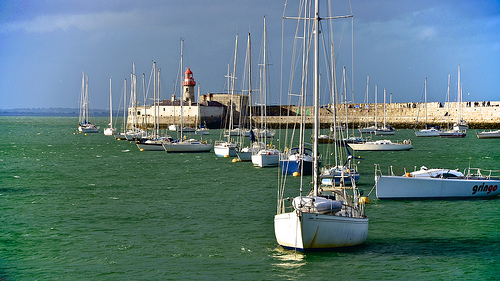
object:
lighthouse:
[182, 68, 194, 85]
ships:
[265, 2, 373, 246]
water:
[1, 160, 206, 279]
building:
[151, 73, 247, 117]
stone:
[132, 92, 245, 132]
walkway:
[228, 96, 500, 127]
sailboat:
[284, 145, 321, 176]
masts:
[289, 1, 344, 199]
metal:
[305, 2, 326, 203]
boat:
[349, 138, 413, 151]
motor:
[403, 138, 411, 145]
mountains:
[2, 103, 136, 119]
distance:
[4, 94, 130, 120]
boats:
[74, 69, 100, 136]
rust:
[277, 237, 367, 249]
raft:
[294, 194, 338, 215]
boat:
[267, 5, 372, 243]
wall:
[241, 111, 500, 132]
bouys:
[232, 157, 238, 163]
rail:
[277, 194, 306, 215]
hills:
[3, 104, 126, 115]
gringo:
[472, 182, 500, 196]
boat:
[374, 162, 493, 197]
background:
[0, 14, 499, 139]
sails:
[294, 5, 351, 211]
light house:
[179, 67, 203, 102]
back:
[134, 65, 495, 105]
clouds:
[2, 2, 490, 126]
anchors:
[360, 195, 370, 208]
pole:
[311, 2, 321, 200]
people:
[174, 115, 450, 122]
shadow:
[311, 231, 494, 257]